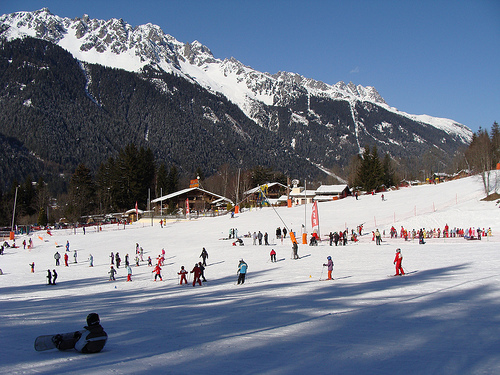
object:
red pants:
[328, 270, 332, 279]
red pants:
[395, 262, 404, 274]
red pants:
[193, 276, 202, 286]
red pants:
[180, 275, 187, 285]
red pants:
[127, 274, 131, 281]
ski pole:
[319, 266, 324, 280]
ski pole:
[266, 256, 271, 263]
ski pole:
[233, 273, 238, 285]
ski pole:
[187, 273, 191, 285]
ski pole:
[178, 274, 180, 285]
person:
[73, 250, 78, 263]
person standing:
[73, 250, 77, 263]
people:
[52, 269, 57, 285]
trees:
[465, 124, 494, 171]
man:
[52, 313, 108, 353]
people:
[177, 266, 188, 285]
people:
[54, 251, 61, 265]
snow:
[0, 170, 497, 373]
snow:
[2, 6, 263, 114]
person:
[270, 249, 276, 262]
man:
[381, 194, 386, 202]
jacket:
[238, 262, 248, 273]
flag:
[311, 200, 321, 240]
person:
[291, 241, 298, 259]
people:
[190, 263, 202, 286]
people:
[151, 263, 162, 282]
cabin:
[429, 173, 452, 184]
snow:
[154, 187, 197, 202]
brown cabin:
[151, 187, 236, 216]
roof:
[151, 187, 233, 204]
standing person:
[419, 228, 425, 244]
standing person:
[29, 238, 33, 248]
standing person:
[264, 232, 270, 245]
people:
[323, 255, 335, 279]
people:
[236, 258, 249, 285]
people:
[199, 247, 209, 266]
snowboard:
[387, 270, 419, 278]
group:
[22, 223, 493, 286]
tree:
[353, 144, 374, 194]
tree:
[364, 143, 385, 193]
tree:
[382, 153, 400, 188]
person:
[393, 248, 405, 276]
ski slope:
[0, 169, 500, 373]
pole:
[11, 187, 18, 231]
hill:
[0, 171, 500, 223]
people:
[419, 229, 425, 244]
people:
[375, 228, 381, 244]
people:
[353, 232, 358, 242]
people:
[334, 233, 340, 246]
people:
[328, 230, 333, 245]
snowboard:
[34, 331, 82, 352]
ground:
[0, 219, 500, 372]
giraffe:
[393, 248, 405, 276]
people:
[108, 266, 117, 281]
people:
[270, 249, 277, 263]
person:
[108, 266, 117, 281]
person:
[199, 247, 209, 266]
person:
[47, 269, 52, 285]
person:
[197, 262, 208, 282]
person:
[126, 264, 133, 282]